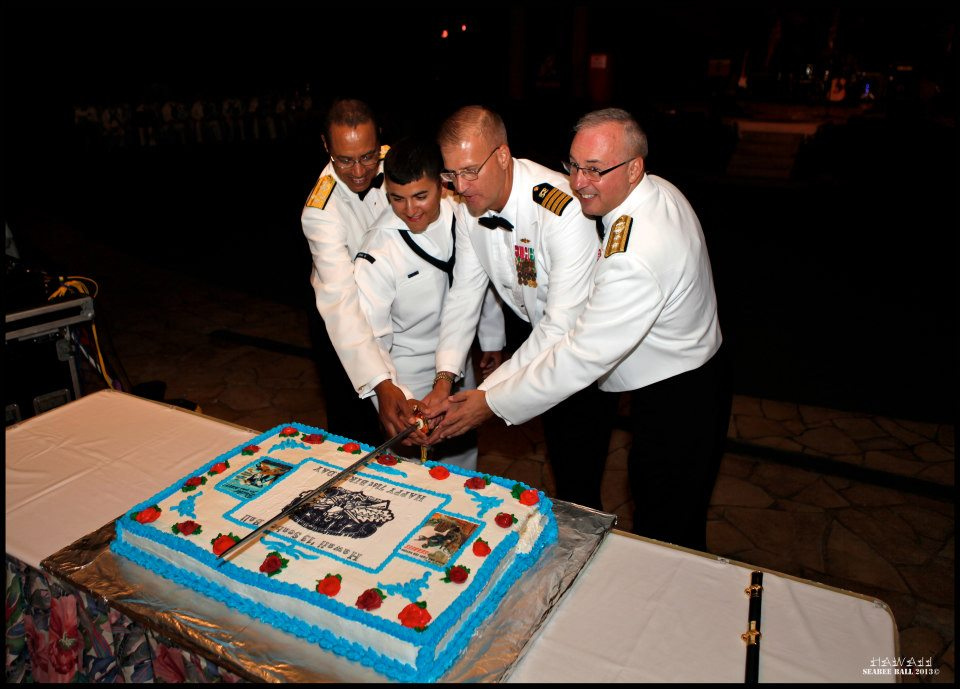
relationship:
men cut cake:
[306, 98, 736, 555] [98, 405, 595, 684]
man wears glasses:
[436, 108, 734, 550] [566, 155, 632, 184]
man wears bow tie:
[430, 91, 583, 309] [467, 211, 519, 237]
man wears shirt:
[287, 91, 391, 396] [292, 173, 396, 403]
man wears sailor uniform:
[369, 150, 452, 307] [360, 213, 452, 321]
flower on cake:
[392, 595, 440, 635] [98, 405, 595, 684]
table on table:
[0, 386, 898, 686] [7, 375, 914, 685]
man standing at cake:
[298, 99, 418, 462] [109, 421, 562, 684]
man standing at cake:
[352, 143, 507, 469] [109, 421, 562, 684]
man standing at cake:
[414, 104, 613, 510] [109, 421, 562, 684]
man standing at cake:
[436, 108, 734, 550] [109, 421, 562, 684]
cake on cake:
[109, 421, 562, 684] [98, 405, 595, 684]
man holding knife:
[298, 99, 418, 462] [212, 411, 437, 569]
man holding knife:
[352, 143, 507, 469] [212, 411, 437, 569]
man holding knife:
[414, 104, 613, 510] [212, 411, 437, 569]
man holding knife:
[436, 108, 734, 550] [212, 411, 437, 569]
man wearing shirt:
[298, 99, 418, 462] [298, 144, 388, 399]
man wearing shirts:
[352, 143, 507, 469] [342, 181, 521, 413]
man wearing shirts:
[414, 104, 613, 510] [418, 136, 632, 424]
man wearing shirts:
[436, 108, 734, 550] [475, 176, 747, 437]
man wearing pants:
[418, 108, 758, 581] [606, 335, 756, 558]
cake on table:
[109, 421, 562, 684] [7, 375, 914, 685]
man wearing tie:
[352, 143, 507, 469] [395, 214, 478, 292]